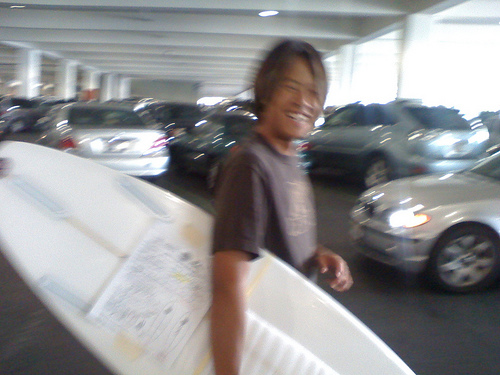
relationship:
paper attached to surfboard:
[87, 216, 215, 372] [1, 139, 418, 375]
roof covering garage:
[2, 2, 460, 99] [1, 2, 498, 375]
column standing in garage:
[15, 48, 40, 102] [1, 2, 498, 375]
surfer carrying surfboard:
[211, 37, 356, 375] [1, 139, 418, 375]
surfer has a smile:
[211, 37, 356, 375] [283, 108, 313, 122]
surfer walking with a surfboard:
[211, 37, 356, 375] [1, 139, 418, 375]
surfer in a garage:
[211, 37, 356, 375] [1, 2, 498, 375]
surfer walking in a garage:
[211, 37, 356, 375] [1, 2, 498, 375]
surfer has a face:
[211, 37, 356, 375] [270, 58, 319, 137]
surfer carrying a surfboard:
[211, 37, 356, 375] [1, 139, 418, 375]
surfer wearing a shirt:
[211, 37, 356, 375] [207, 130, 321, 285]